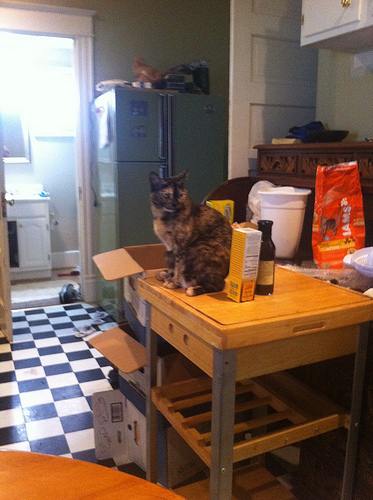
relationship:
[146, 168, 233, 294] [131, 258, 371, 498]
cat sitting on table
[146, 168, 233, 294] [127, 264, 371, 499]
cat sitting on cart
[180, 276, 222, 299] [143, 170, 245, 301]
tail on cat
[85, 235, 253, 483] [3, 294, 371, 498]
boxes on floor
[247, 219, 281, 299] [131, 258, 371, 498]
bottle on table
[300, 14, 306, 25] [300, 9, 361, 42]
knob on door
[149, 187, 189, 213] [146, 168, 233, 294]
face of cat